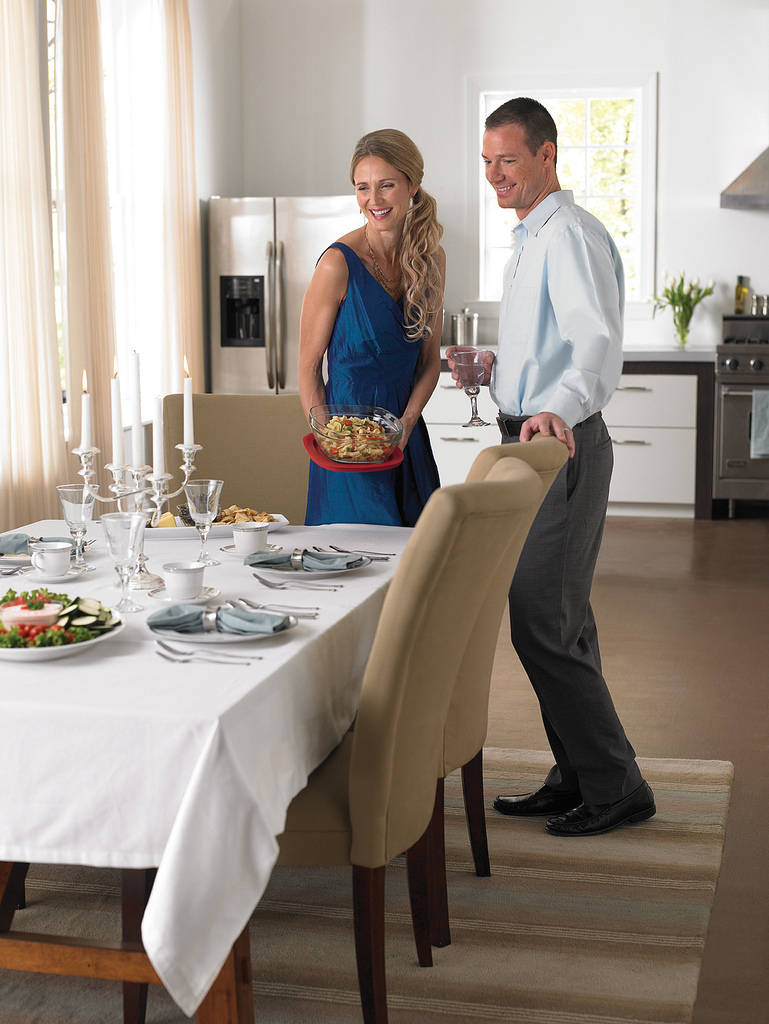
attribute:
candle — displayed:
[164, 346, 216, 477]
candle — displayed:
[72, 371, 111, 450]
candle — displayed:
[52, 379, 72, 438]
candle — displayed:
[147, 389, 167, 483]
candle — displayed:
[72, 375, 92, 454]